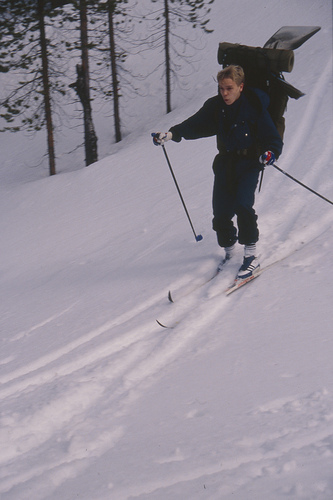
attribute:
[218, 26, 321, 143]
backpack — brown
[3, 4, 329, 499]
snow — white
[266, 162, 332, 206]
pole — black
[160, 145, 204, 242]
pole — black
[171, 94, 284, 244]
skisuit — blue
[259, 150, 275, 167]
glove — red, white, blue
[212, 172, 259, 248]
pants — black, blue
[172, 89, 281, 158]
jacket — blue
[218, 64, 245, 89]
hair — blond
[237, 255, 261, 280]
boot — white, blue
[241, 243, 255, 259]
sock — white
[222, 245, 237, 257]
sock — white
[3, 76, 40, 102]
branch — thin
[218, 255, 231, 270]
boot — blue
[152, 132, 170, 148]
glove — blue, white